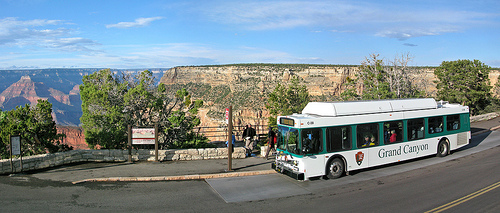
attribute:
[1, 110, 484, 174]
wall — low, stone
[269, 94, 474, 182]
bus — white, stopped, large, white and green, green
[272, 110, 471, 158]
trim — green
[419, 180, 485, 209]
double line — yellow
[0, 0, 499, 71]
sky — blue 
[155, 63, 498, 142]
plateau — light brown 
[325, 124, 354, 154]
window — large , wide 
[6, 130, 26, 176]
sign — small , wooden 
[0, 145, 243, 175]
wall — stone , short , rock 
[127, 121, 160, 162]
sign — wooden , large 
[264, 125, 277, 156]
man — walking 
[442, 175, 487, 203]
lines — yellow, double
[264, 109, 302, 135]
window — digital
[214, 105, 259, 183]
pole — wooden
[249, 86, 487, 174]
bus — white, green, tour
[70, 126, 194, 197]
wall — stone, short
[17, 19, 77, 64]
sky — blue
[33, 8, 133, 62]
clouds — whispy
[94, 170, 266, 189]
curb — concrete, road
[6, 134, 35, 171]
sign — white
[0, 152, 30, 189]
poles — wooden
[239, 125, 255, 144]
jacket — black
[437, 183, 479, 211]
lines — yellow, painted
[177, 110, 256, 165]
barrier — protective metal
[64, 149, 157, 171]
wall — light colored, rock, retaining wall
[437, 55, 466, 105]
tree — large, green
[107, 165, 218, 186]
curb — yellow, fading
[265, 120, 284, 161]
sleeves — red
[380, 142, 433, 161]
grand canyon — large view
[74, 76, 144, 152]
tree — green roadside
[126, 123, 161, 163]
poles — wood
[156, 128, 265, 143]
fence — metal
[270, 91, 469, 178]
bus — white, green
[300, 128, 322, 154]
window — green